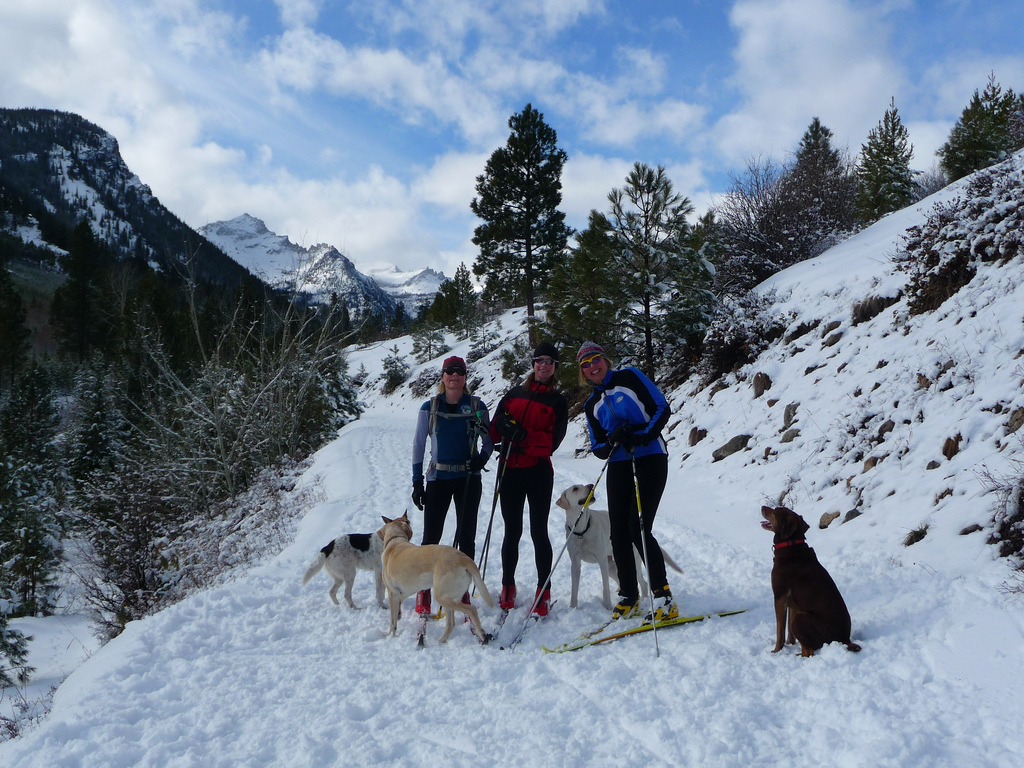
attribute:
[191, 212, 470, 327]
mountains — are snow covered, are rocky 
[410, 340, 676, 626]
people — wearing ski clothes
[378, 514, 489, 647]
dog — short haired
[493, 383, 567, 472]
jacket — red, black 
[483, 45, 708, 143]
cloud — White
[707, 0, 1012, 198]
cloud — White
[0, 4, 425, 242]
cloud — White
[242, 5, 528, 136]
cloud — White 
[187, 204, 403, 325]
mountain — Snow capped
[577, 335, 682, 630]
skiier — posing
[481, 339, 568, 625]
skiier — posing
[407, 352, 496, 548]
skiier — posing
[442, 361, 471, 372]
sunglasses — black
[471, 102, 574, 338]
pine — tall, green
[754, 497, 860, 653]
dog — brown, sitting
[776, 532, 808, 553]
collar — red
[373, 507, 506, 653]
dog — light brown, blonde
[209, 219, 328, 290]
snow — white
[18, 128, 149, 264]
snow — white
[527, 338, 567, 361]
hat — black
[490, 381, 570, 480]
jacket — red, black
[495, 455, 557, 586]
pants — black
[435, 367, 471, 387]
sunglasses — black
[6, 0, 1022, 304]
sky — blue 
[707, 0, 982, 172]
cloud — white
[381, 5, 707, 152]
cloud — white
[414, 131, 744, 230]
cloud — white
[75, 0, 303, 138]
cloud — white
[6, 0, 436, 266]
cloud — white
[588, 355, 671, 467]
jacket — white, blue, black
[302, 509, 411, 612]
dog — black, white